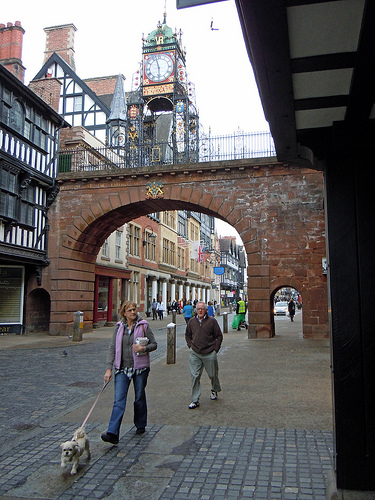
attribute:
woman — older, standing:
[93, 296, 163, 458]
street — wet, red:
[27, 334, 141, 474]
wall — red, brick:
[217, 195, 338, 347]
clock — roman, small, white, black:
[138, 50, 178, 96]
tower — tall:
[129, 4, 204, 145]